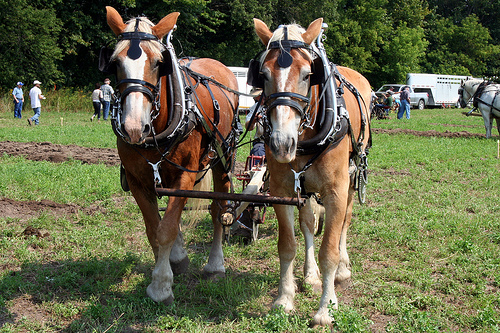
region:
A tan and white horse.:
[248, 18, 372, 326]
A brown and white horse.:
[106, 6, 238, 307]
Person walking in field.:
[25, 80, 46, 128]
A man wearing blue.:
[9, 80, 26, 118]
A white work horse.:
[457, 71, 499, 141]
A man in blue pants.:
[396, 86, 413, 120]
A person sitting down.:
[373, 90, 393, 119]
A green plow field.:
[1, 110, 499, 332]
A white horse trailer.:
[408, 70, 470, 106]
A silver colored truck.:
[372, 82, 429, 110]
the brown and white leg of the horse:
[118, 153, 176, 269]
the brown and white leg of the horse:
[149, 148, 203, 307]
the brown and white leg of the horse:
[205, 145, 232, 272]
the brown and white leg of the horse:
[266, 157, 302, 318]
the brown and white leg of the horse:
[309, 149, 349, 323]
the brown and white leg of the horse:
[295, 188, 321, 294]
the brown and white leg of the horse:
[333, 178, 353, 288]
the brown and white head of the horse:
[112, 20, 159, 140]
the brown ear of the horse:
[104, 8, 122, 30]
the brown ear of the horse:
[152, 10, 180, 39]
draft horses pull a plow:
[104, 5, 369, 325]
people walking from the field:
[12, 77, 117, 127]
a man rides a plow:
[247, 83, 270, 157]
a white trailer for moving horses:
[219, 64, 259, 111]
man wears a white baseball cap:
[31, 76, 43, 88]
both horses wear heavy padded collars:
[111, 37, 191, 148]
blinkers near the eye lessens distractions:
[244, 55, 264, 90]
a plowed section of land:
[3, 138, 120, 164]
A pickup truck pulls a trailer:
[371, 84, 431, 109]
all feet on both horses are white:
[141, 234, 351, 316]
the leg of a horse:
[260, 180, 302, 318]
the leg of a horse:
[310, 187, 350, 328]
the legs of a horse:
[137, 168, 228, 303]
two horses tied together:
[91, 3, 377, 323]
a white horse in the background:
[452, 70, 497, 140]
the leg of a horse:
[475, 108, 495, 138]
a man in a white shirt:
[27, 85, 43, 108]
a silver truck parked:
[367, 83, 432, 113]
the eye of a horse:
[257, 68, 269, 84]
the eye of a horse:
[298, 67, 312, 84]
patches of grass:
[386, 209, 488, 314]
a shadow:
[196, 282, 238, 317]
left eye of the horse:
[151, 48, 164, 71]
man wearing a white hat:
[34, 80, 46, 85]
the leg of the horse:
[318, 238, 348, 323]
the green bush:
[362, 27, 419, 64]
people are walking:
[92, 79, 114, 125]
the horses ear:
[308, 17, 325, 44]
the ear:
[247, 18, 271, 44]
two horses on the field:
[54, 15, 379, 200]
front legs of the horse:
[248, 217, 370, 297]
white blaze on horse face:
[106, 43, 168, 147]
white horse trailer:
[406, 71, 478, 109]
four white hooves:
[268, 217, 353, 326]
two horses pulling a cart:
[101, 4, 376, 331]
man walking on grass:
[26, 77, 48, 128]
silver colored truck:
[374, 81, 430, 111]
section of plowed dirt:
[1, 137, 121, 165]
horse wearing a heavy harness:
[454, 72, 499, 140]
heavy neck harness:
[244, 17, 352, 167]